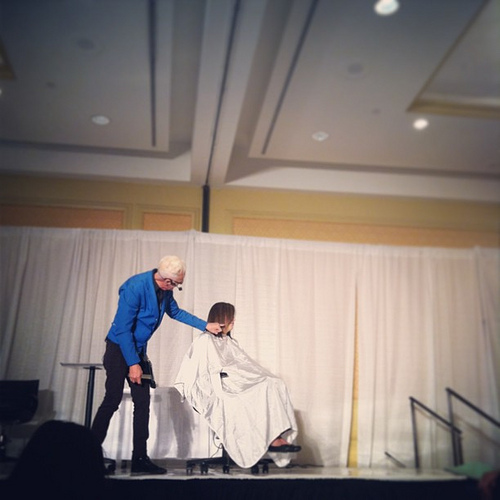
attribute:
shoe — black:
[275, 437, 315, 461]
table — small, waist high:
[61, 362, 104, 427]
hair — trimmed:
[166, 258, 177, 274]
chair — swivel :
[183, 442, 276, 475]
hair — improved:
[204, 295, 233, 335]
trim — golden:
[0, 169, 499, 253]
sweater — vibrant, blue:
[94, 267, 214, 403]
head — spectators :
[8, 416, 106, 486]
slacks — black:
[91, 338, 151, 455]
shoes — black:
[99, 455, 167, 474]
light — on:
[408, 115, 433, 142]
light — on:
[310, 123, 330, 145]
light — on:
[370, 0, 405, 21]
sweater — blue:
[105, 267, 207, 366]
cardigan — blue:
[109, 265, 182, 390]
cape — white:
[177, 324, 310, 459]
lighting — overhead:
[398, 94, 448, 141]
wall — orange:
[2, 201, 498, 249]